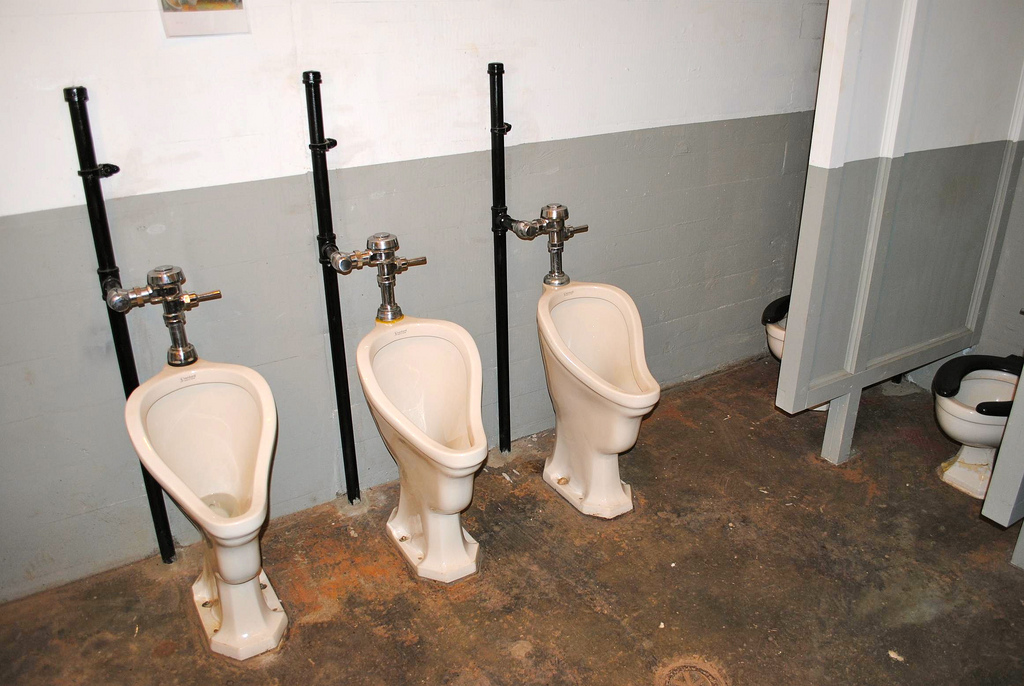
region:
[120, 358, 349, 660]
white toilet in bathroom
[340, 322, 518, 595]
white toilet in bathroom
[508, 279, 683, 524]
white toilet in bathroom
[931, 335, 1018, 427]
black toilet seat on toilet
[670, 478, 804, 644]
brown floor in room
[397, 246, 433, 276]
silver handle on toilet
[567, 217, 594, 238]
silver handle on toilet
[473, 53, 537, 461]
black pole behind toilet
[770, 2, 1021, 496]
Wooden partition wall that is half white and half gray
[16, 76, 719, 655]
Three men's urinals in a line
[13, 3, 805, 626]
Cement block wall that is half white and half gray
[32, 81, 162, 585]
Dark metal plumbing pipe of urinal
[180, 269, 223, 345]
Metal flushing handle on urinal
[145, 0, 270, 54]
Piece of paper on wall in men's restroom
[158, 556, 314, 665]
Floor base with four bolt holes on urinal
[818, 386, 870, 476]
Post supporting wood dividing wall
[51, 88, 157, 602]
Black pipe near wall.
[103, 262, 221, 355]
Silver flusher on urinal.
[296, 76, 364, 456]
Black pipe near wall.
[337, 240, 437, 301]
Silver flusher on urinal.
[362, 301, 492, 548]
White urinal near wall.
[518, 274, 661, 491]
White urinal near wall.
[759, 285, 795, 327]
Black seat on toilet.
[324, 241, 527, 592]
A white open toiled.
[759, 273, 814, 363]
A white open toiled.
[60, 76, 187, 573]
A long black pole.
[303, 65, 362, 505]
A long black pole.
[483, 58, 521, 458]
A long black pole.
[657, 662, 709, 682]
A drain in the floor.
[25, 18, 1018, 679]
Public toilet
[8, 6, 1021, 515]
Grey and white paint on the walls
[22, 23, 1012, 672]
Gents rest room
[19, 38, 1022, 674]
Urinals and toilets in the restroom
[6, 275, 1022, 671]
Brown concrete floor in the restroom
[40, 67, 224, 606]
Stainless steel flush and black water pipe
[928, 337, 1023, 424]
White porcelain toilet and black seat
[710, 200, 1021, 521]
Two toilets near the right side wall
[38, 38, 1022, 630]
Men's restroom with urinals and toilets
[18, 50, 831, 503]
A white and gray wall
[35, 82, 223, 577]
The black pipe to the left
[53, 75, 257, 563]
A black pipe to the left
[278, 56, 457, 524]
The black pipe in the middle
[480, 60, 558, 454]
The black pipe to the right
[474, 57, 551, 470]
A black pipe to the right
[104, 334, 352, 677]
The white toilet to the left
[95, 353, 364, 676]
A white toilet to the left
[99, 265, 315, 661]
white ceramic standing urinal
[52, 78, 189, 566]
Black metal water pipe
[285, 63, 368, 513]
Black metal water pipe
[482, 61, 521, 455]
Black metal water pipe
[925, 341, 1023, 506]
white ceramic toilet bowl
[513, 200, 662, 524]
White ceramic standing urinal